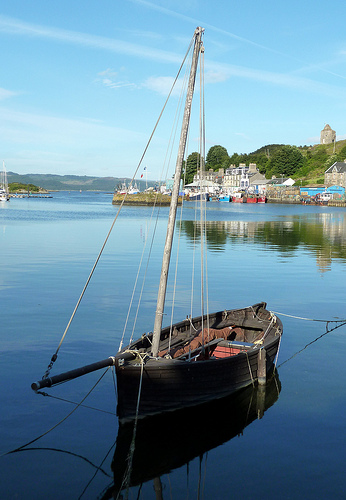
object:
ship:
[30, 20, 282, 427]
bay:
[0, 194, 345, 499]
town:
[179, 159, 269, 202]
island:
[112, 183, 183, 207]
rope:
[268, 307, 345, 326]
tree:
[206, 143, 231, 170]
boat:
[216, 191, 231, 203]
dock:
[184, 192, 218, 203]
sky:
[1, 1, 343, 182]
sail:
[161, 324, 234, 360]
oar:
[173, 335, 224, 362]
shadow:
[111, 371, 287, 486]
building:
[299, 183, 345, 201]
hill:
[208, 140, 342, 178]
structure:
[317, 123, 338, 147]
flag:
[143, 165, 147, 171]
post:
[145, 166, 148, 190]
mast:
[149, 26, 203, 357]